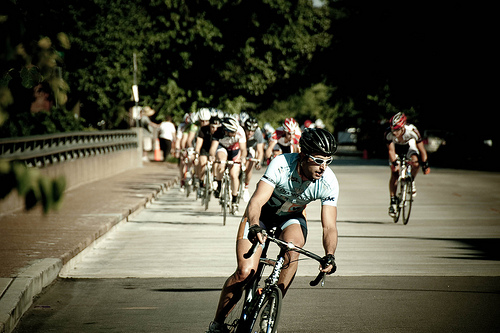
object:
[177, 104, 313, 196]
people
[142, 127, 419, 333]
racers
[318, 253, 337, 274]
gloves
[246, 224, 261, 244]
gloves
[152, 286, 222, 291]
shadow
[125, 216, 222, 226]
shadow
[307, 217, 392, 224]
shadow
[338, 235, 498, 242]
shadow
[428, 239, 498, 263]
shadow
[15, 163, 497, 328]
pavement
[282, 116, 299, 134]
helmet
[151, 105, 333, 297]
bus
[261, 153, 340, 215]
shirt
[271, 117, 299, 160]
people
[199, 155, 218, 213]
bicycle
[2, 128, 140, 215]
railing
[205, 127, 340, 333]
bicyclist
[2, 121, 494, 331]
bridge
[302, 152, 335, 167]
sunglasses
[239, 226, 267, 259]
handlebar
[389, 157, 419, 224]
bicycle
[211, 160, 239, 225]
bicycle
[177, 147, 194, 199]
bicycle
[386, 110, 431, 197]
people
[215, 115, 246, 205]
people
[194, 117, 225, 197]
people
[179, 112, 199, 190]
people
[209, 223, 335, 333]
bicycle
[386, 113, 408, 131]
helmet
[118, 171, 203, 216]
shadows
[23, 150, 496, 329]
ground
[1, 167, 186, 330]
sidewalk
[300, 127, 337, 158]
helmet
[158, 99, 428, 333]
people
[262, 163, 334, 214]
dark graphics